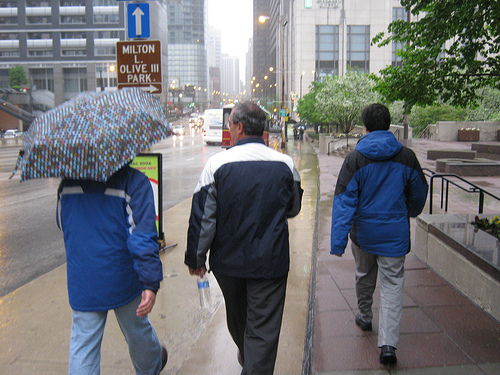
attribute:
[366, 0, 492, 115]
leaves — green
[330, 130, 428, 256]
coat — blue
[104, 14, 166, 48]
sign — blue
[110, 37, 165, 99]
sign — brown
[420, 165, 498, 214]
stair rails — black, metal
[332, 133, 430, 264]
jacket — blue and black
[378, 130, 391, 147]
ground — white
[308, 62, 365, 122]
flowers — white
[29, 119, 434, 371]
sidewalk — concrete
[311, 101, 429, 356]
man — black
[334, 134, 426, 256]
jacket — blue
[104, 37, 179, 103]
sign — brown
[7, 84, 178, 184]
umbrella — open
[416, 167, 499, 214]
railing — metal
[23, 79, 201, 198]
colored umbrella — multicolored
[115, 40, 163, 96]
sign — brown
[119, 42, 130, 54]
letter — white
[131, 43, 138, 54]
letter — white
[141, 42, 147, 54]
letter — white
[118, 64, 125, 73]
letter — white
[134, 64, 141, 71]
letter — white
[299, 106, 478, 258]
jacket — blue and white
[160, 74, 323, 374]
man — bald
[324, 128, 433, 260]
coat — black, blue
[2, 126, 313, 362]
street — city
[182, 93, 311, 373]
man — white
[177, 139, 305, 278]
jacket — white, blue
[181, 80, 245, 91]
street lights — on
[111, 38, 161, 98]
sign — brown and white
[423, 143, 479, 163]
bench — stone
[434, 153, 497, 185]
bench — stone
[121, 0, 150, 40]
sign — blue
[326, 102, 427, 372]
man — black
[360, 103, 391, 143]
hair — dark